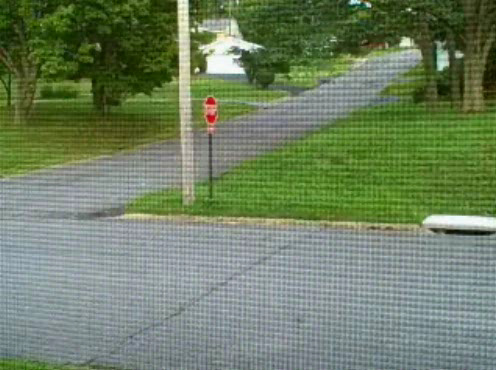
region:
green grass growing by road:
[238, 151, 435, 227]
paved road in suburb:
[16, 197, 407, 365]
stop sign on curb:
[200, 90, 222, 199]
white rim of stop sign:
[199, 99, 213, 120]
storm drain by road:
[422, 228, 494, 242]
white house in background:
[179, 17, 265, 73]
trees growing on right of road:
[418, 14, 494, 111]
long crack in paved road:
[65, 197, 327, 367]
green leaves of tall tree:
[373, 7, 433, 33]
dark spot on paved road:
[282, 311, 330, 330]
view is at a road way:
[106, 51, 473, 318]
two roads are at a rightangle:
[91, 166, 304, 355]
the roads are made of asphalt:
[163, 260, 332, 369]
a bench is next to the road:
[431, 210, 491, 234]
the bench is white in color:
[421, 184, 494, 227]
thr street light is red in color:
[197, 91, 237, 209]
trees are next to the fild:
[65, 12, 157, 130]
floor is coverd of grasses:
[324, 138, 419, 211]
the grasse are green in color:
[303, 146, 397, 222]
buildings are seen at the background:
[205, 31, 280, 85]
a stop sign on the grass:
[195, 51, 233, 204]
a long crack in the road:
[97, 234, 269, 353]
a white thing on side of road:
[407, 204, 494, 244]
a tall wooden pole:
[149, 7, 207, 220]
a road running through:
[212, 60, 382, 164]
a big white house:
[183, 5, 282, 83]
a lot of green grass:
[300, 120, 452, 214]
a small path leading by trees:
[215, 76, 322, 127]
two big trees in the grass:
[5, 11, 157, 144]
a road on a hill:
[280, 46, 427, 92]